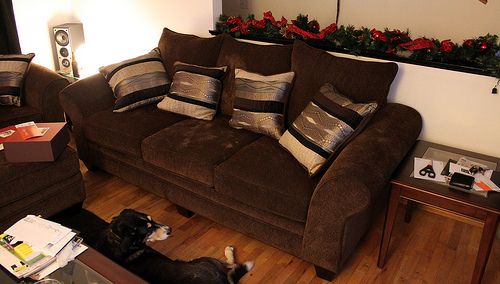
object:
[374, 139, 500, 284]
end table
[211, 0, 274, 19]
corner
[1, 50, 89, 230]
chair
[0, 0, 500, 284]
living room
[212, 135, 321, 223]
cushions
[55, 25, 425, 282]
couch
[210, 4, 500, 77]
planter box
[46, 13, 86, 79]
speaker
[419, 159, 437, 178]
scissors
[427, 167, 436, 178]
handle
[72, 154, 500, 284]
floor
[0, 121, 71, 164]
box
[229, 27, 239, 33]
flowers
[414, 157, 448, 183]
papers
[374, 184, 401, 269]
legs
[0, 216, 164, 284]
table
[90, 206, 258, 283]
dog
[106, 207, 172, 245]
head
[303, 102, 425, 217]
arm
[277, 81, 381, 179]
cushion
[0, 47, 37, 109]
throw pillow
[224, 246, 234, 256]
foot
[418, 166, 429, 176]
handles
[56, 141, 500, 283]
ground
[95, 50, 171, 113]
accent pillows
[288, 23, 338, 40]
garland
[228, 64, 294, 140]
cushion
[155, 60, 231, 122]
cushion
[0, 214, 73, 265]
books